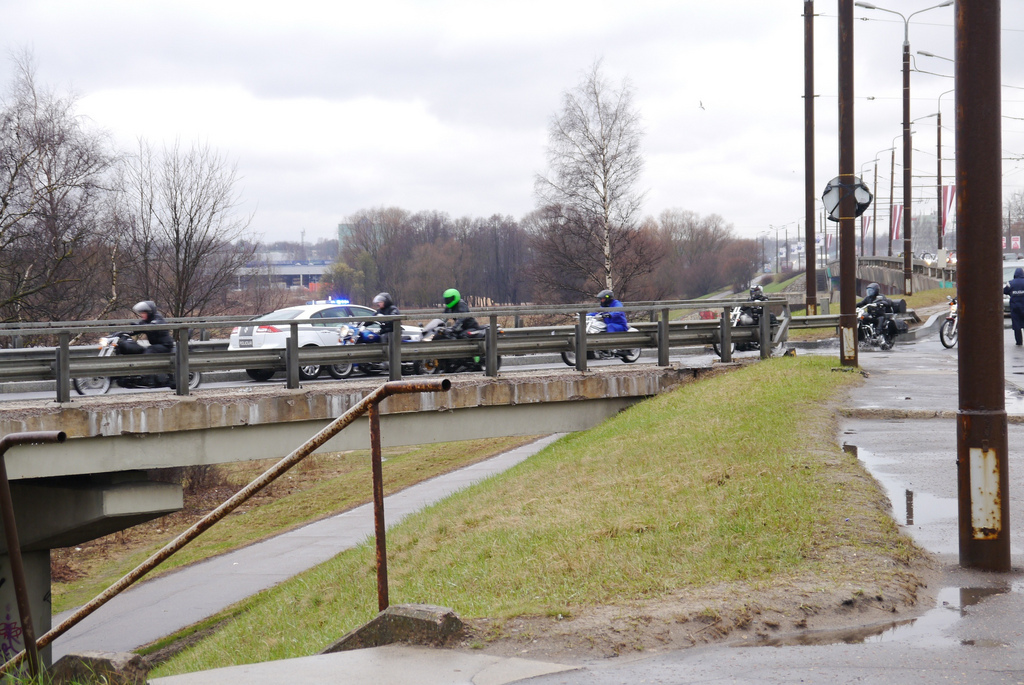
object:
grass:
[131, 354, 911, 679]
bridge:
[0, 297, 792, 673]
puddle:
[857, 447, 959, 554]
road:
[840, 268, 1023, 547]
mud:
[463, 588, 942, 666]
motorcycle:
[72, 301, 203, 396]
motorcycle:
[413, 288, 504, 375]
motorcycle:
[714, 283, 786, 356]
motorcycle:
[855, 283, 909, 352]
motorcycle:
[941, 295, 958, 349]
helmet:
[595, 289, 612, 307]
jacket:
[586, 300, 629, 331]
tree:
[512, 55, 666, 301]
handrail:
[0, 378, 452, 678]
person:
[586, 289, 629, 332]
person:
[740, 283, 768, 319]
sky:
[0, 0, 1024, 247]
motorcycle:
[561, 312, 641, 366]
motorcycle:
[714, 306, 786, 357]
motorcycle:
[855, 296, 909, 350]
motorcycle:
[413, 319, 504, 376]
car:
[227, 300, 424, 381]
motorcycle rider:
[443, 288, 481, 339]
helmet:
[443, 288, 462, 308]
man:
[112, 301, 173, 353]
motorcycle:
[72, 334, 201, 395]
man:
[362, 292, 405, 335]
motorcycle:
[328, 315, 421, 380]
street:
[0, 340, 818, 440]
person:
[855, 283, 885, 336]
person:
[952, 296, 958, 300]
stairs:
[46, 603, 463, 684]